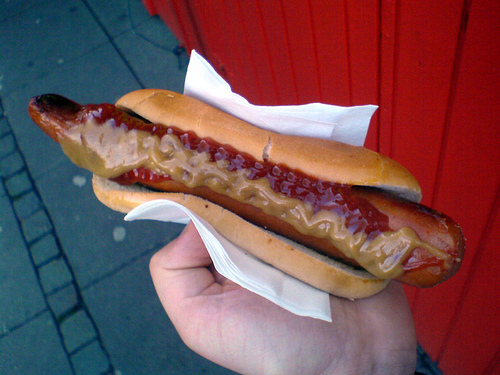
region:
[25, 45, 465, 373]
hotdog in a person's hand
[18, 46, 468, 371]
hotdog being held in someone's hand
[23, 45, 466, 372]
hotdog and napkin in a hand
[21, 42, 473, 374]
napking and hotdog in a person's hand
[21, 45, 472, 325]
hotdog on top of a napkin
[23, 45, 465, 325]
napkin underneath a well cooked hot dog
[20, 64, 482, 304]
grilled hot dog topped with ketchup and mustard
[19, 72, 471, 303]
ketchup and mustard topping a hot dog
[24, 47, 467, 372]
hot dog being held out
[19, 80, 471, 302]
grilled hot dog in a bun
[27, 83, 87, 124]
burnt area of hot dog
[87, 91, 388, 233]
ketchup drizzled on hot dog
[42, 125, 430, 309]
mustard drizzled on hot dog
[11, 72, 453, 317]
delicious looking hot dog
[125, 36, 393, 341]
white napkin under hotdog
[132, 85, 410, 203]
hot dog bun with hot dog in it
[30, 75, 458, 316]
hot dog in person's hand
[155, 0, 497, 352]
red wall behind hotdog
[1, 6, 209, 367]
grey side walk under hotdog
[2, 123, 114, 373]
line of square cement blocks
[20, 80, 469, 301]
a hot dog on a bun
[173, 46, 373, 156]
a napkin around a hot dog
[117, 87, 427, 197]
the top of a hot dog bun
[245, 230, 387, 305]
the bottom of a hot dog bun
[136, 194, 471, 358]
a hand holding a hot dog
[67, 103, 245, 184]
condiments on top of a hot dog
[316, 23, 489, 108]
a red wooden wall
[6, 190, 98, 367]
a cement side walk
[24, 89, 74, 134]
the burnt end of a hot dogs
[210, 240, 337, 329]
a napkin wrapped around a hot dogs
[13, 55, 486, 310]
The hot dog has mustard on it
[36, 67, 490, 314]
The hot dog has ketchup on it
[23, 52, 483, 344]
The hot dog has ketchup and mustard on it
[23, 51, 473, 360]
A hand is holding the hot dog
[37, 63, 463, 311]
The hot dog is big in length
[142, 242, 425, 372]
Palm of a person's hand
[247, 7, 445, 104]
The wall is red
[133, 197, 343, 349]
A napkin is under the hot dog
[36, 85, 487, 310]
The bun is outside the meat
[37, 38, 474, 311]
The person is using a napkin to hold the hot dog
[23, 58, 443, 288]
hot dog in the photo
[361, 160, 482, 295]
end of the hot dog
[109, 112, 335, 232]
ketchup on the hot dog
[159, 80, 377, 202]
bun on the hot dog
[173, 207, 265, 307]
white napkin under hot dog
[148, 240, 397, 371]
hand of the person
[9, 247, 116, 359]
lines on the ground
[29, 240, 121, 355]
dark ground in photo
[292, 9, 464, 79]
red wall next to hot dog